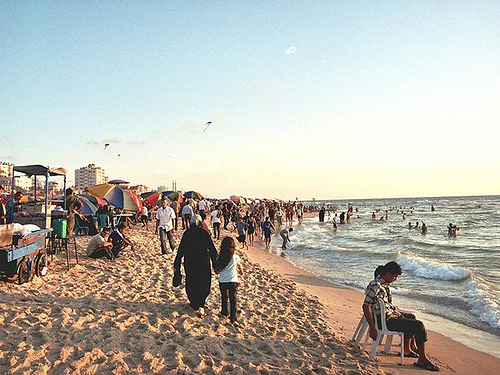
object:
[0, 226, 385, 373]
tracks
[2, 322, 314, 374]
sand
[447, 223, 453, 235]
person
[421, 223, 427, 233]
person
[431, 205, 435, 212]
person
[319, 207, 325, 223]
person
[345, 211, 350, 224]
person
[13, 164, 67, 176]
canopy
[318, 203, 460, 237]
people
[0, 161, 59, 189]
tall building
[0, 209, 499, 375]
shore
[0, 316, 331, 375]
ground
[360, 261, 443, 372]
people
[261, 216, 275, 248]
people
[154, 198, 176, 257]
people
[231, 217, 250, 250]
people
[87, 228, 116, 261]
people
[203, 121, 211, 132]
kite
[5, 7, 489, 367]
air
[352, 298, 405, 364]
chair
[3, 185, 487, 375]
beach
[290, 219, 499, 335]
water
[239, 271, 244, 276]
girl's hand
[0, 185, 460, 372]
people gathering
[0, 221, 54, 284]
cart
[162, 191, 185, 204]
umbrellas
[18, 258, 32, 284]
wheel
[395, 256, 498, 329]
wave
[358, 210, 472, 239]
wet people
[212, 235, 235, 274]
hair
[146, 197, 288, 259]
people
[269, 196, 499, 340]
ocean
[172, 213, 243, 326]
people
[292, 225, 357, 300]
coastal area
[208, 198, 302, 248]
some people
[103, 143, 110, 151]
kites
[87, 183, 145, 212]
umbrella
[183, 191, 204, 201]
umbrella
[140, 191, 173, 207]
umbrella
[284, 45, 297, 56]
cloud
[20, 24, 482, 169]
sky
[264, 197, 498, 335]
tide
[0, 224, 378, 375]
footprints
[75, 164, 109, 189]
building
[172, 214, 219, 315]
woman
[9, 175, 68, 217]
stand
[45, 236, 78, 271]
stand